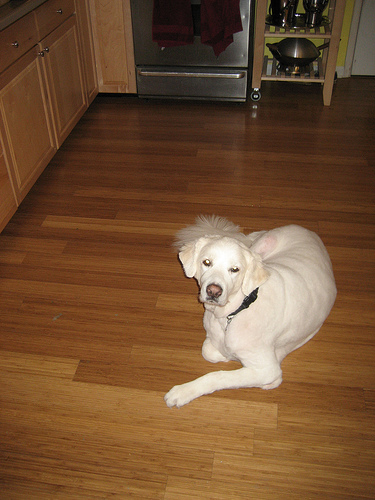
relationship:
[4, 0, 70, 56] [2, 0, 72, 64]
knobs are on drawers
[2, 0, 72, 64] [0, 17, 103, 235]
drawers are over cabinets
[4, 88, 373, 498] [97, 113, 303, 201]
floor made of boards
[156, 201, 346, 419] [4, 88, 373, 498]
dog on floor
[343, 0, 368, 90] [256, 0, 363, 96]
trim around wall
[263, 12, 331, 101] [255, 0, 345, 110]
shelves are on rack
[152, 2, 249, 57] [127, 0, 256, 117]
towel on oven door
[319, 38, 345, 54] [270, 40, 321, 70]
handle on wok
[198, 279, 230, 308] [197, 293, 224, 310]
nose over mouth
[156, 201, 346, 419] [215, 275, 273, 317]
dog wearing a collar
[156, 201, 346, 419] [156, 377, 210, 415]
dog has a paw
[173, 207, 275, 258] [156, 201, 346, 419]
tail on dog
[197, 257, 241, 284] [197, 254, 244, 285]
camera flash in eyes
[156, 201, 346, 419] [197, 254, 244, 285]
dog has eyes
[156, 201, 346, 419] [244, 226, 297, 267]
dog has leg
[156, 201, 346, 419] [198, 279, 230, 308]
dog has a nose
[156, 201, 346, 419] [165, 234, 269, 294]
dog has ears